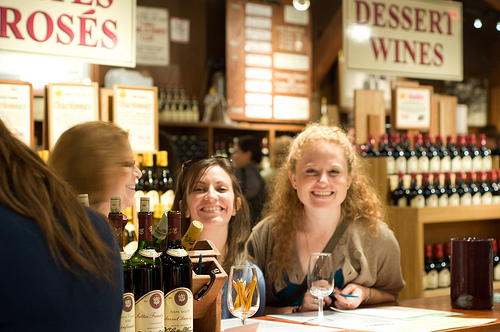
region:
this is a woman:
[249, 115, 377, 251]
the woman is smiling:
[308, 185, 340, 195]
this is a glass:
[292, 247, 339, 320]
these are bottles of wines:
[126, 206, 188, 311]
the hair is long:
[273, 177, 288, 250]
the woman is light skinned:
[312, 207, 329, 232]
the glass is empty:
[298, 251, 338, 317]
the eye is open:
[216, 184, 227, 197]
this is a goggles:
[179, 152, 231, 157]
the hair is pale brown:
[269, 182, 289, 247]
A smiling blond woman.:
[244, 123, 405, 314]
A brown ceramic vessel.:
[449, 236, 492, 309]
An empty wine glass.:
[304, 251, 336, 325]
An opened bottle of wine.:
[159, 210, 193, 330]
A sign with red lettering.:
[0, 0, 136, 69]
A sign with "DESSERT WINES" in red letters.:
[342, 0, 462, 81]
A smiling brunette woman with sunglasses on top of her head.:
[169, 154, 266, 319]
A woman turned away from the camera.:
[0, 119, 125, 331]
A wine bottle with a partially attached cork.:
[130, 196, 165, 331]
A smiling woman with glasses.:
[47, 120, 142, 217]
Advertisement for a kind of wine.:
[2, 4, 139, 75]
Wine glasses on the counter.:
[228, 258, 343, 326]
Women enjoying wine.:
[3, 113, 406, 330]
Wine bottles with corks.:
[77, 191, 211, 330]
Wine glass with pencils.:
[225, 263, 269, 326]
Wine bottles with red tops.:
[358, 121, 498, 221]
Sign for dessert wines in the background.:
[339, 3, 469, 85]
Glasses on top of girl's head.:
[173, 155, 239, 176]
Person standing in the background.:
[226, 129, 271, 200]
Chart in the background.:
[222, 1, 327, 136]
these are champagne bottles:
[117, 197, 197, 328]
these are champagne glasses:
[219, 251, 345, 316]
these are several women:
[6, 132, 401, 302]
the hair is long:
[274, 202, 293, 277]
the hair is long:
[302, 127, 342, 137]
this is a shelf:
[402, 213, 420, 288]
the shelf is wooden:
[396, 213, 422, 227]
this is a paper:
[379, 310, 419, 330]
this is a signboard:
[344, 2, 468, 78]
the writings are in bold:
[378, 10, 441, 68]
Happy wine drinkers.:
[28, 115, 422, 244]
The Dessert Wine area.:
[324, 0, 498, 102]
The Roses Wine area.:
[6, 1, 163, 83]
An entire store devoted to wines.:
[0, 31, 498, 330]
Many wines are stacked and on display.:
[347, 114, 498, 329]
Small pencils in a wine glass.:
[216, 254, 278, 321]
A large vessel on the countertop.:
[443, 220, 499, 323]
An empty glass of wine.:
[297, 239, 341, 309]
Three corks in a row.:
[74, 186, 154, 209]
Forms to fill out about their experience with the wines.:
[212, 293, 496, 330]